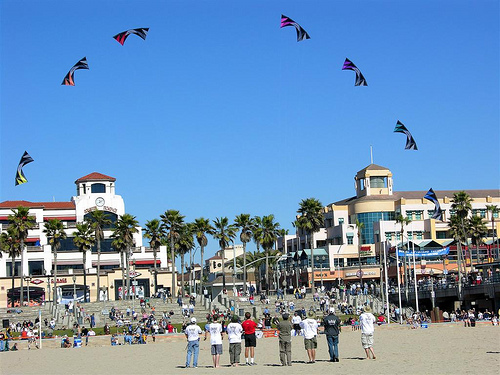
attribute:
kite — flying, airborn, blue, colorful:
[279, 12, 312, 44]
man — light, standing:
[184, 316, 203, 369]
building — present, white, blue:
[1, 171, 171, 277]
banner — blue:
[397, 246, 449, 259]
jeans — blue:
[326, 331, 340, 361]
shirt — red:
[241, 319, 257, 335]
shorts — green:
[303, 336, 318, 351]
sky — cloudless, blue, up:
[2, 0, 498, 213]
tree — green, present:
[206, 217, 235, 296]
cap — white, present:
[326, 307, 337, 315]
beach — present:
[0, 321, 498, 375]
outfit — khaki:
[277, 319, 295, 366]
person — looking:
[298, 310, 319, 364]